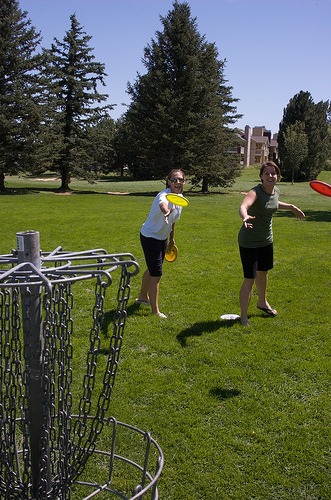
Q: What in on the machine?
A: Chains.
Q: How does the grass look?
A: Well kept.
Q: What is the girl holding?
A: Yellow frisbee.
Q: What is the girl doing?
A: Throwing frisbee.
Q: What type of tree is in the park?
A: Pine tree.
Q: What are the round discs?
A: Frisbees.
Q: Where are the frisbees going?
A: Towards goals.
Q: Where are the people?
A: In park.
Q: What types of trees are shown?
A: Pine.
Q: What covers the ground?
A: Grass.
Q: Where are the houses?
A: Behind trees.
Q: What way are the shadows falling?
A: Left.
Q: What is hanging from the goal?
A: Chains.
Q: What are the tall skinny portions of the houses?
A: Chimneys.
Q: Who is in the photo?
A: Two women.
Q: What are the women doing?
A: Playing Frisbee.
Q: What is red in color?
A: Frisbee.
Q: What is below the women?
A: Grass.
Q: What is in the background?
A: Trees.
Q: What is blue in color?
A: The sky.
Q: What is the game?
A: Frisbee golf.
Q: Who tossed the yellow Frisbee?
A: The girl on the left.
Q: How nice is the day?
A: Clear bright and sunny.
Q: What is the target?
A: The basket with chains.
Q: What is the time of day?
A: Daytime.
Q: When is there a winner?
A: Lowest par.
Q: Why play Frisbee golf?
A: Fun and exercise.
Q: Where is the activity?
A: Golf Frisbee.